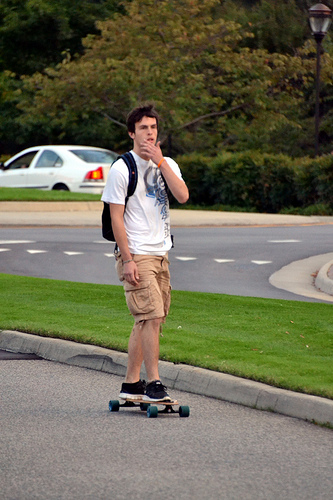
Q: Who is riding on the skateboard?
A: A young boy.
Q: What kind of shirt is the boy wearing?
A: White shirt with gray and blue design on the front.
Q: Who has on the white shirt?
A: The boy.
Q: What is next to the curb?
A: Short grass.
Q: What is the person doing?
A: Riding a skateboard.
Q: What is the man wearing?
A: A white shirt.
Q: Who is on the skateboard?
A: A guy.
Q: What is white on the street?
A: Street lines.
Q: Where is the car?
A: Street.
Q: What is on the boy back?
A: Backpack.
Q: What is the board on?
A: Pavement.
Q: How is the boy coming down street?
A: Skateboard.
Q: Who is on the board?
A: Boy.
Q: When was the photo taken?
A: Daytime.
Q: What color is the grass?
A: Green.